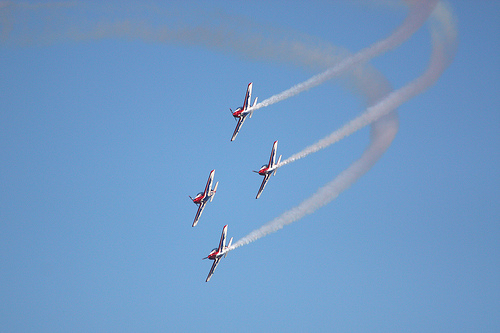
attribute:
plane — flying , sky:
[257, 140, 282, 200]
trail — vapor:
[276, 3, 462, 158]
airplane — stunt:
[223, 77, 262, 144]